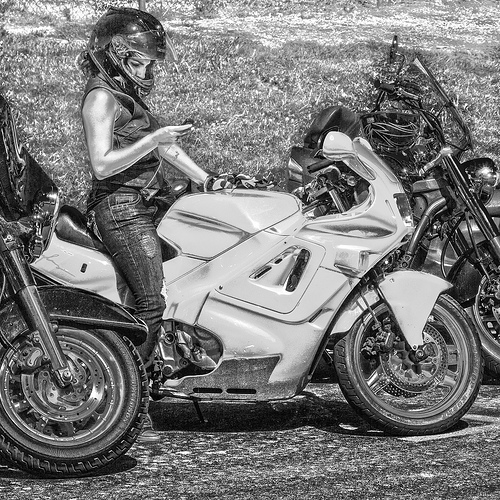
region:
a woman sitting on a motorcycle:
[40, 10, 495, 437]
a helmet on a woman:
[83, 6, 168, 103]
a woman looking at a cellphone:
[80, 8, 208, 199]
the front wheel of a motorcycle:
[339, 273, 481, 428]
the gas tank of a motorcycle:
[158, 179, 294, 257]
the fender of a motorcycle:
[377, 268, 461, 347]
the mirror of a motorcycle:
[323, 130, 354, 165]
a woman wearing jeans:
[76, 6, 191, 356]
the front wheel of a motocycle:
[2, 280, 151, 485]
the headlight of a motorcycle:
[391, 186, 412, 231]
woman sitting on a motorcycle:
[10, 8, 482, 484]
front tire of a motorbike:
[335, 256, 482, 438]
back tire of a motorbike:
[2, 279, 158, 483]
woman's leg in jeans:
[82, 173, 171, 369]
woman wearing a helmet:
[77, 8, 166, 100]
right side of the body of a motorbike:
[180, 178, 345, 391]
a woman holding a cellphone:
[81, 8, 203, 175]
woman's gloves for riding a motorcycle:
[204, 163, 284, 200]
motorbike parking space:
[221, 369, 492, 499]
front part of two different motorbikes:
[302, 67, 496, 448]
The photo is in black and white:
[0, 8, 498, 494]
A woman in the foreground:
[48, 3, 275, 394]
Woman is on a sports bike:
[25, 7, 485, 458]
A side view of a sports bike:
[38, 131, 483, 452]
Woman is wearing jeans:
[93, 178, 195, 373]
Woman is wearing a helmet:
[78, 2, 170, 102]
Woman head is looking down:
[71, 9, 173, 106]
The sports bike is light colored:
[19, 118, 452, 407]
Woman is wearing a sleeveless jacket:
[61, 63, 189, 195]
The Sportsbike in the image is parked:
[11, 130, 486, 433]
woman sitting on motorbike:
[72, 27, 183, 308]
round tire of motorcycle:
[29, 314, 164, 458]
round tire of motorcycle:
[334, 330, 486, 465]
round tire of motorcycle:
[453, 257, 499, 316]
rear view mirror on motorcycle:
[325, 130, 362, 165]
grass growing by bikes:
[171, 39, 289, 134]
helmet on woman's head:
[79, 10, 174, 81]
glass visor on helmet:
[127, 25, 200, 84]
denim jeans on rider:
[101, 204, 161, 280]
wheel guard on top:
[384, 240, 468, 365]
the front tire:
[450, 393, 470, 414]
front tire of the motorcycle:
[120, 415, 140, 436]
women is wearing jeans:
[113, 213, 157, 260]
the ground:
[218, 446, 308, 496]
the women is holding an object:
[170, 115, 197, 137]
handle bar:
[308, 154, 329, 172]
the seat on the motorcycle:
[67, 210, 92, 235]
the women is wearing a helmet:
[103, 3, 173, 102]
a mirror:
[385, 30, 403, 60]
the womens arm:
[86, 99, 112, 164]